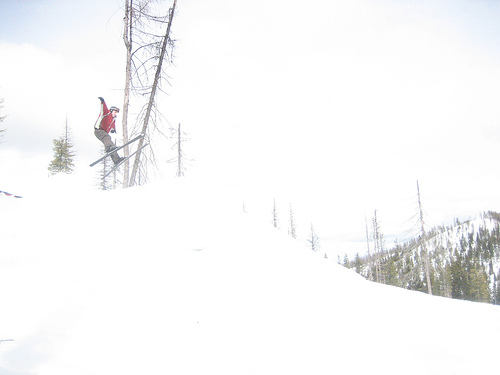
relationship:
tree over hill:
[113, 2, 173, 176] [94, 172, 310, 372]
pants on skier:
[94, 131, 124, 170] [86, 94, 136, 175]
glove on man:
[94, 95, 110, 102] [87, 95, 124, 170]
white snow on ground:
[418, 313, 470, 354] [0, 277, 500, 374]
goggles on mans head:
[109, 106, 121, 112] [104, 102, 121, 119]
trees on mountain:
[371, 242, 498, 303] [338, 210, 499, 306]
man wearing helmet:
[93, 96, 127, 164] [108, 103, 121, 114]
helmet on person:
[109, 103, 119, 113] [92, 95, 127, 167]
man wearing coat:
[93, 96, 127, 164] [94, 97, 118, 135]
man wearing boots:
[93, 96, 127, 164] [104, 145, 126, 169]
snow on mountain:
[13, 159, 495, 355] [3, 19, 498, 353]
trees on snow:
[367, 210, 497, 302] [2, 189, 499, 371]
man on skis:
[93, 96, 127, 164] [89, 135, 150, 180]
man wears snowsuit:
[93, 96, 127, 164] [89, 103, 121, 157]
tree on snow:
[47, 111, 77, 174] [23, 237, 308, 359]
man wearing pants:
[93, 96, 127, 164] [86, 126, 145, 178]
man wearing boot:
[93, 96, 127, 164] [110, 151, 129, 167]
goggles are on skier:
[110, 107, 120, 111] [82, 90, 143, 165]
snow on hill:
[0, 174, 500, 375] [2, 181, 499, 369]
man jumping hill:
[93, 96, 127, 164] [2, 181, 499, 369]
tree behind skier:
[50, 132, 74, 169] [80, 91, 152, 169]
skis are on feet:
[84, 135, 150, 172] [104, 147, 125, 167]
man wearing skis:
[93, 96, 127, 164] [92, 136, 169, 181]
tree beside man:
[90, 119, 143, 187] [87, 95, 134, 170]